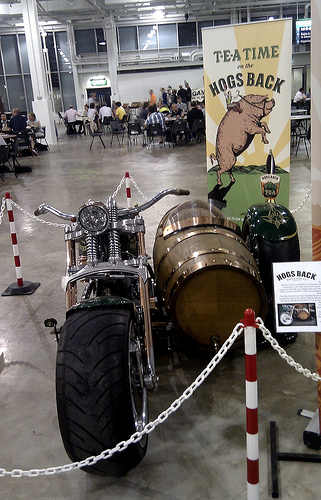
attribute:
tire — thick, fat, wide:
[62, 328, 184, 451]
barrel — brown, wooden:
[148, 209, 236, 307]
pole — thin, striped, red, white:
[231, 308, 296, 499]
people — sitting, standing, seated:
[95, 97, 190, 145]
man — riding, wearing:
[218, 86, 248, 130]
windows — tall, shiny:
[50, 32, 75, 113]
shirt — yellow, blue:
[113, 102, 138, 114]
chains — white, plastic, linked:
[28, 416, 165, 493]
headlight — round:
[59, 206, 102, 223]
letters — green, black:
[199, 37, 290, 66]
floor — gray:
[55, 163, 164, 181]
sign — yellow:
[182, 29, 317, 195]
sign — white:
[272, 242, 309, 297]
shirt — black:
[169, 91, 219, 105]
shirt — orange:
[145, 93, 177, 115]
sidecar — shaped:
[145, 209, 293, 290]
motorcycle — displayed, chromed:
[43, 194, 196, 467]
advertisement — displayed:
[204, 60, 308, 190]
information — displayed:
[258, 270, 312, 331]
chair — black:
[144, 127, 177, 149]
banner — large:
[178, 47, 319, 178]